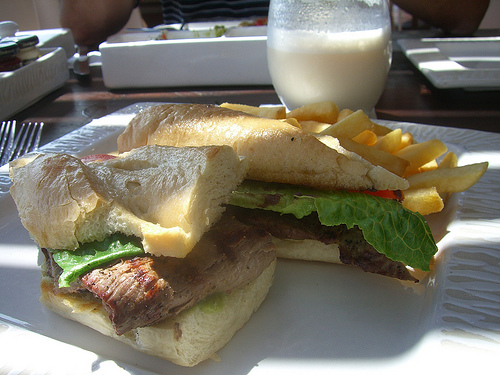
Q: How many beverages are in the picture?
A: One.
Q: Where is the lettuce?
A: On the sandwich.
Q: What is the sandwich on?
A: A plate.